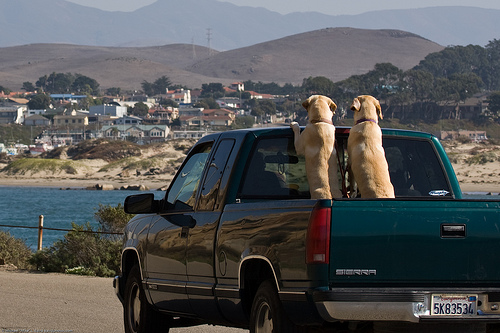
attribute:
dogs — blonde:
[298, 97, 376, 204]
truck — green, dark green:
[136, 116, 493, 330]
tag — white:
[433, 288, 482, 320]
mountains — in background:
[10, 3, 496, 105]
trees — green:
[298, 40, 489, 118]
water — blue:
[3, 171, 126, 229]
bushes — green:
[12, 209, 137, 269]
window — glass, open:
[158, 147, 223, 203]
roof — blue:
[202, 120, 431, 146]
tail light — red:
[309, 203, 345, 275]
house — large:
[82, 118, 191, 145]